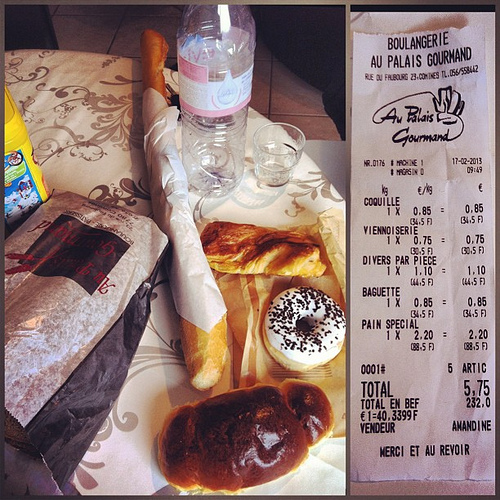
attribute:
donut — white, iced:
[267, 287, 343, 380]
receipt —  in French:
[351, 23, 496, 482]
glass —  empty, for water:
[244, 105, 321, 187]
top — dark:
[178, 410, 300, 465]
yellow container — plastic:
[0, 90, 47, 215]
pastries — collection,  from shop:
[99, 21, 335, 491]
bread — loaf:
[125, 33, 225, 369]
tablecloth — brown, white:
[31, 72, 123, 165]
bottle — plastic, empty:
[175, 4, 255, 197]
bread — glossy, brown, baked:
[153, 375, 334, 495]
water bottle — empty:
[176, 3, 258, 202]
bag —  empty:
[4, 187, 170, 427]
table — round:
[3, 47, 348, 498]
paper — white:
[141, 86, 229, 333]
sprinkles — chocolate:
[298, 283, 328, 306]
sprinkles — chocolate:
[269, 288, 339, 353]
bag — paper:
[7, 137, 179, 459]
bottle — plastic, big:
[169, 7, 257, 199]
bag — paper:
[191, 228, 352, 435]